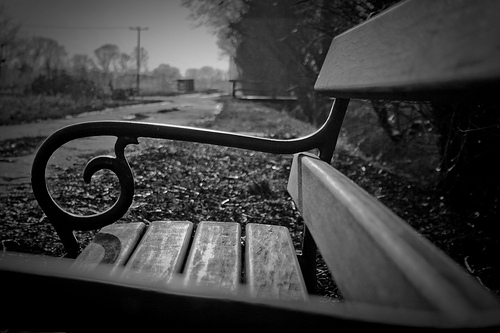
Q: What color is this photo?
A: Black and white.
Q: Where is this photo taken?
A: By a sidewalk.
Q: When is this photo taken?
A: Daytime.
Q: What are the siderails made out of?
A: Metal.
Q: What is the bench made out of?
A: Wood.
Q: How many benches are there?
A: One.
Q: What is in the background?
A: A sidewalk.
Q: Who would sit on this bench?
A: Someone walking.